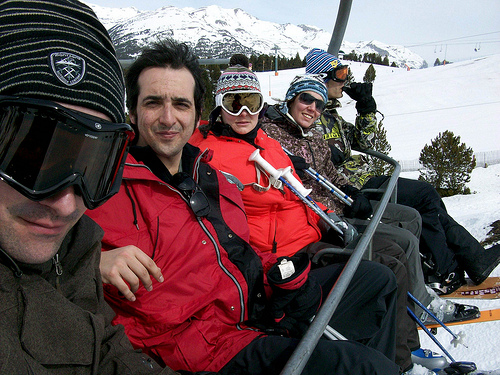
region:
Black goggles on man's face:
[0, 90, 135, 216]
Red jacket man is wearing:
[64, 130, 275, 372]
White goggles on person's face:
[211, 84, 270, 118]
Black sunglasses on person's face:
[292, 89, 329, 116]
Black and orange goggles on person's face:
[327, 62, 353, 84]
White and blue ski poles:
[252, 150, 463, 366]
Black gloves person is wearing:
[336, 77, 393, 120]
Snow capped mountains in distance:
[97, 6, 455, 81]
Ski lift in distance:
[390, 30, 499, 62]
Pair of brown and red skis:
[414, 263, 498, 302]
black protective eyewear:
[0, 93, 130, 205]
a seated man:
[0, 0, 160, 374]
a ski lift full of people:
[0, 0, 496, 371]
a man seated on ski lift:
[95, 43, 407, 374]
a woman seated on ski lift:
[196, 50, 476, 374]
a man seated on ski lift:
[297, 42, 497, 297]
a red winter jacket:
[77, 125, 274, 370]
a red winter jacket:
[186, 118, 333, 288]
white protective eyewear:
[215, 89, 261, 114]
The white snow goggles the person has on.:
[209, 90, 268, 118]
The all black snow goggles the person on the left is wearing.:
[2, 93, 135, 213]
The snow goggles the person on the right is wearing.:
[330, 62, 353, 82]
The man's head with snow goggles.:
[125, 37, 202, 160]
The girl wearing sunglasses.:
[294, 87, 333, 119]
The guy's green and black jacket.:
[317, 101, 379, 177]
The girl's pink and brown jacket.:
[272, 102, 338, 209]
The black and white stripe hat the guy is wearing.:
[2, 0, 127, 124]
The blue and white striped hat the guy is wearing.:
[301, 40, 341, 72]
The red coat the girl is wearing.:
[182, 112, 323, 254]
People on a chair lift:
[3, 5, 498, 374]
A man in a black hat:
[3, 6, 132, 267]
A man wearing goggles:
[3, 78, 135, 222]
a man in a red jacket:
[99, 46, 251, 361]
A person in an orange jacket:
[190, 64, 302, 275]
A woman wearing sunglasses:
[276, 61, 327, 143]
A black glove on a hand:
[338, 61, 384, 131]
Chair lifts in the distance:
[385, 38, 498, 64]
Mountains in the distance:
[85, 3, 437, 65]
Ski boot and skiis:
[403, 281, 499, 338]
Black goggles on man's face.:
[26, 99, 134, 174]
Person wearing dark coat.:
[40, 297, 122, 341]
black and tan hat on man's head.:
[15, 23, 88, 98]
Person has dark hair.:
[136, 43, 229, 90]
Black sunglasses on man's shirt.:
[165, 164, 252, 228]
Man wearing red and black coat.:
[129, 191, 294, 335]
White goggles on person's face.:
[218, 77, 272, 122]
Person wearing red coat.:
[229, 152, 294, 241]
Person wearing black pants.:
[306, 272, 373, 357]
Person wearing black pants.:
[423, 177, 483, 314]